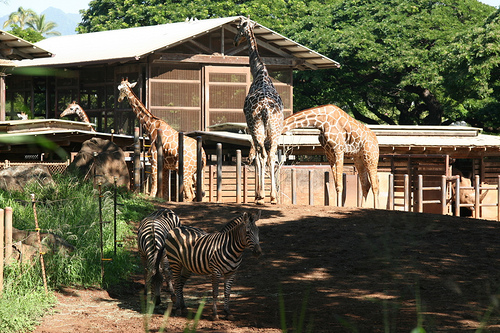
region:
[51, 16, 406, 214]
FOUR GIRAFFES IN THE SUN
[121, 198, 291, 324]
TWO ZEBRAS STANDING TOGETHER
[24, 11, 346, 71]
THE ROOF OF A BUILDING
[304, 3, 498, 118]
TREES IN THE BACKGROUND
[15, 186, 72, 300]
A FENCE POLE IN THE GROUND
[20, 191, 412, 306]
A WIRE FENCE BETWEEN THE ZEBRAS AND GIRAFFES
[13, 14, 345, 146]
A BUILDING IN THE BACKGROUND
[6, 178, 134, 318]
GRASS IN THE SUN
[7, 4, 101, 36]
THE SKY PEAKING THROUGH THE TREES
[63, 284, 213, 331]
A DIRT COVERED GROUND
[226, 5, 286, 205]
A tall giraffe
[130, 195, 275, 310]
Two zebras standing together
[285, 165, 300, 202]
A wooden fence post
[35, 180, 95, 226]
A patch of tall grass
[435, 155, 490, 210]
A rhinoceros in a pen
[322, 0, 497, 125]
A very large tree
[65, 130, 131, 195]
A large brown rock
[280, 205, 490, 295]
A large patch of dirt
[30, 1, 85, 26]
A range of distant mountains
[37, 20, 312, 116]
A tall building with a white roof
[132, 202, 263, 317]
these are two zebras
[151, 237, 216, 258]
the fur is black and white in color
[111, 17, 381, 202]
these are giraffes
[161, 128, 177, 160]
the fur is brown and white in color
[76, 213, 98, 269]
this is the grass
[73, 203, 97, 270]
the grass is green in color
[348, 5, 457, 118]
these are several trees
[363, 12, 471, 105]
the leaves are green in color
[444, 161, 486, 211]
this is a rhino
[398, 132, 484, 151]
the shed is wooden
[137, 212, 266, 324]
these are two zebars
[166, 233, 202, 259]
the fur has dirt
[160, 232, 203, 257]
the fur is white and black in color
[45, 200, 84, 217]
this is the grass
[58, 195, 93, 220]
the grass is green in color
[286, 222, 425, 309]
this is the ground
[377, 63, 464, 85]
the trees are green in color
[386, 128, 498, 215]
this is a shed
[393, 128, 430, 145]
the shed is wooden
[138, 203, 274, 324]
A pair of zebras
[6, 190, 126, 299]
A small section of grass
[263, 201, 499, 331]
A huge patch of dirt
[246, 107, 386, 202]
A giraffe with his head down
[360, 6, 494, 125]
A small section of a large tree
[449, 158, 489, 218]
A rhino in the barn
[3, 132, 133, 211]
Two rocks in the grass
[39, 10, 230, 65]
Roof of a barn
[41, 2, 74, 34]
A sky with a cloud